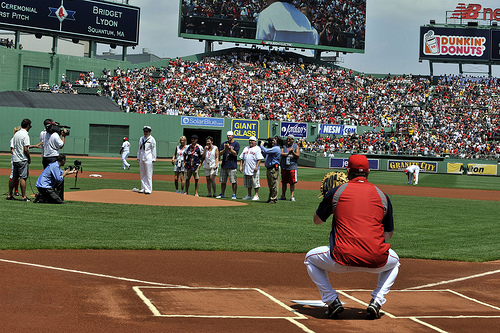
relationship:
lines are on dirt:
[0, 255, 499, 328] [0, 246, 498, 333]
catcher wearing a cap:
[301, 151, 400, 318] [345, 153, 370, 173]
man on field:
[9, 117, 35, 200] [2, 155, 499, 332]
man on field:
[116, 135, 132, 172] [2, 155, 499, 332]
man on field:
[237, 135, 264, 206] [2, 155, 499, 332]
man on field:
[277, 132, 302, 203] [2, 155, 499, 332]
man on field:
[217, 130, 241, 202] [2, 155, 499, 332]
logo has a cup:
[423, 29, 486, 57] [421, 30, 439, 56]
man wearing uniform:
[137, 124, 158, 200] [135, 135, 157, 194]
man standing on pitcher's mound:
[137, 124, 158, 200] [60, 185, 248, 209]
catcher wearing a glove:
[301, 151, 400, 318] [322, 171, 336, 197]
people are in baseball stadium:
[35, 50, 495, 159] [1, 45, 498, 159]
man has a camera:
[35, 117, 66, 200] [43, 124, 70, 136]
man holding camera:
[35, 117, 66, 200] [43, 124, 70, 136]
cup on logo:
[421, 30, 439, 56] [423, 29, 486, 57]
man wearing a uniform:
[137, 124, 158, 200] [135, 135, 157, 194]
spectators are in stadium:
[35, 50, 495, 159] [1, 45, 498, 159]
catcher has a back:
[301, 151, 400, 318] [330, 180, 387, 263]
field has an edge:
[2, 155, 499, 332] [1, 152, 499, 181]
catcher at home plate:
[301, 151, 400, 318] [292, 297, 349, 310]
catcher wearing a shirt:
[301, 151, 400, 318] [315, 178, 395, 272]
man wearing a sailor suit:
[137, 124, 158, 200] [135, 135, 157, 194]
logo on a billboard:
[423, 29, 486, 57] [417, 22, 497, 66]